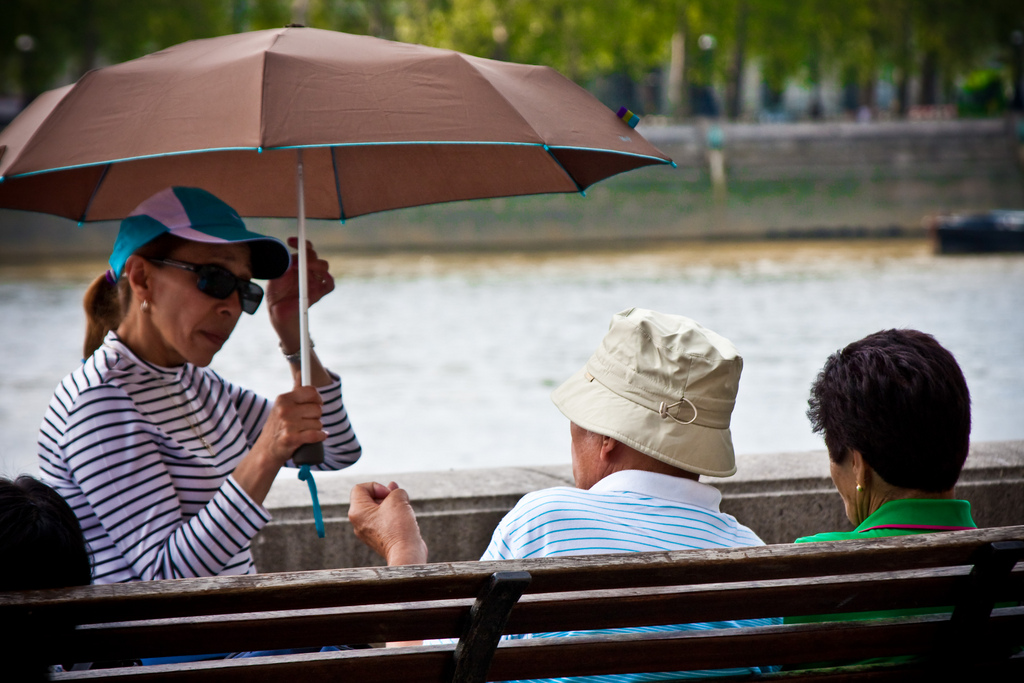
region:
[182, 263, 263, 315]
the shades are black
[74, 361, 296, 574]
the shirt is striped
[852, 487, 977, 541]
the shirt is green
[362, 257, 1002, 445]
the water is silver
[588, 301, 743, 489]
the hat is tan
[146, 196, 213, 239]
stripe on the hat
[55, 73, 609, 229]
the umbrella is brown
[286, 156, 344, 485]
handle under the umbrella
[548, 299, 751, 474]
tan hat on person head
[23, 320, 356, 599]
white shirt with black stripes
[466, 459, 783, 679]
blue shirt with black stripe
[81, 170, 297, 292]
blue and pink ball cap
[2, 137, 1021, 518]
flowing waterway at a park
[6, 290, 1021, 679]
couple sitting on wooden park bench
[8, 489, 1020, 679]
wooden park bench facing river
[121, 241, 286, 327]
black sunglasses with dark shades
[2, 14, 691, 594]
A woman holding an umbrella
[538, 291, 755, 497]
A beige hat on a head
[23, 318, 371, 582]
A black and white striped shirt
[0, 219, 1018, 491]
The water appears to be calm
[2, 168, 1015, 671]
People sitting on a bench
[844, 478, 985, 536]
Green collar of a shirt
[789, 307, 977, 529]
Person has black hair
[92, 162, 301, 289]
A blue and pink hat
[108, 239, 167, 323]
Earring in an ear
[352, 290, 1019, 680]
Two people sitting on a bench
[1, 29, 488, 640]
Woman holding an umbrella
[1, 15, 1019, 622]
Woman talking to two people on a bench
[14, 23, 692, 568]
Woman holding a brown umbrella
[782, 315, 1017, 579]
Person wearing a green shirt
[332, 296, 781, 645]
Person wearing a light tan hat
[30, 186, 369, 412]
Woman wearing a blue and pink hat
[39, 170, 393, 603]
Woman wearing a striped shirt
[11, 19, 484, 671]
Woman standing in front of the water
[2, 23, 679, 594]
woman holding a tan umbrella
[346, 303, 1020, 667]
two people sitting on a wooden bench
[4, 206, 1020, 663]
people sitting along a waterway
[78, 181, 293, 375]
woman wearing black sunglasses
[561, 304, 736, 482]
The bucket hat on the person's head.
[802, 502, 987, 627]
The green shirt the person is wearing.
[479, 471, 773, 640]
The white and light blue collar shirt the person is wearing.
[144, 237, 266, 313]
The sunglasses the woman is wearing.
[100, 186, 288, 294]
The hat the woman is wearing.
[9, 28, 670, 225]
The umbrella over the woman's head.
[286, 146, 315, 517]
The pole of the umbrella.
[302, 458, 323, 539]
The wrist strap of the umbrella.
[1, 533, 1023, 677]
The bench the people are sitting on.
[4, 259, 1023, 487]
The water in front of where the people are sitting.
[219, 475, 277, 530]
black strip on white shirt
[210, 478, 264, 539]
black strip on white shirt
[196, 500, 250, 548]
black strip on white shirt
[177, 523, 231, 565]
black strip on white shirt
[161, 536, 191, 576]
black strip on white shirt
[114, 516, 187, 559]
black strip on white shirt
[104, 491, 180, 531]
black strip on white shirt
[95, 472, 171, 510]
black strip on white shirt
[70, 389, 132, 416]
black stripe on suit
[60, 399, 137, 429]
black stripe on suit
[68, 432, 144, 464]
black stripe on suit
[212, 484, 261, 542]
black stripe on suit